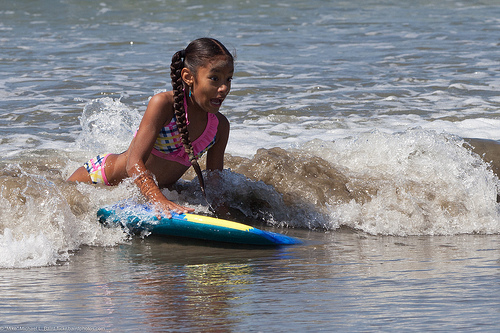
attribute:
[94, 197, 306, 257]
board — blue, yellow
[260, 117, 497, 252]
water — white, brown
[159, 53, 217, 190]
braid — long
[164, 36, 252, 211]
hair — girls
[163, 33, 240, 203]
hair — long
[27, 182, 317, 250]
surfboard — small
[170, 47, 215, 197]
hair — long, braided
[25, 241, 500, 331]
shore — dark, wet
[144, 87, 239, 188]
top — pink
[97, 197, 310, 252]
float — yellow, blue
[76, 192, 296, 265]
surfboard — blue, yellow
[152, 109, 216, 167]
bathingsuit — pink, bathing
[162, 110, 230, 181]
stripes — blue, yellow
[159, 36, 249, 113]
face — surprised, excitement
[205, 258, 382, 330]
water — shallow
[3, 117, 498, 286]
wave — crashed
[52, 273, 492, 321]
water — white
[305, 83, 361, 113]
foam — white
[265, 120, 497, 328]
water — brown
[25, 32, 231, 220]
girl — young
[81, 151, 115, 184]
bottom — yellow, pink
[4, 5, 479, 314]
water — smooth, foamy